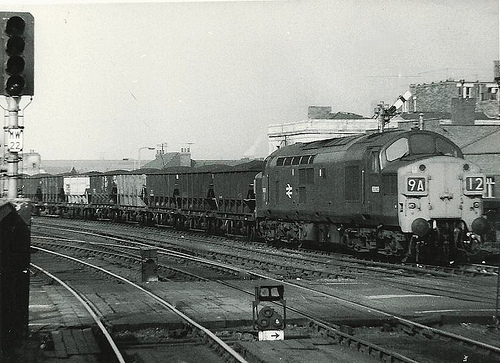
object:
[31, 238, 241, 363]
railtracks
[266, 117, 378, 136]
building top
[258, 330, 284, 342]
sign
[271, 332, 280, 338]
arrow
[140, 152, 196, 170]
roof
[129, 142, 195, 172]
building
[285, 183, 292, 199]
white logo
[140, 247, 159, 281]
box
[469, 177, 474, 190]
number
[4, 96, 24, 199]
pole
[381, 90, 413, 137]
shoot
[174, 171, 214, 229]
train car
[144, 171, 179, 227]
train car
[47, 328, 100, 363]
wood planks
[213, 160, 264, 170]
coal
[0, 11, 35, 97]
light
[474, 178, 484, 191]
number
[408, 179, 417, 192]
number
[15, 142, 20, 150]
number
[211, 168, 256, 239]
train car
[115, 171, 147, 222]
train car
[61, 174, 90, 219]
train car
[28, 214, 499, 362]
track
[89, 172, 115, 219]
train car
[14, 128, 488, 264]
train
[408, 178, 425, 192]
9a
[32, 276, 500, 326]
road